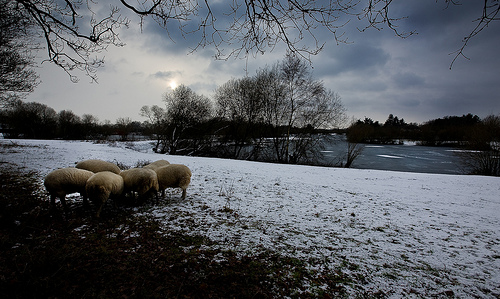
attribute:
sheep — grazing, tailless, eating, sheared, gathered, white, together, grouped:
[42, 157, 189, 219]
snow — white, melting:
[3, 136, 499, 297]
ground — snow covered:
[1, 139, 500, 298]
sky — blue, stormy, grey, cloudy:
[0, 0, 498, 122]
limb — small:
[112, 1, 177, 22]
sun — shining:
[162, 75, 181, 94]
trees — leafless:
[142, 61, 355, 167]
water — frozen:
[118, 136, 499, 174]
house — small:
[100, 125, 125, 142]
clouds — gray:
[108, 10, 264, 87]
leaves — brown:
[1, 171, 285, 296]